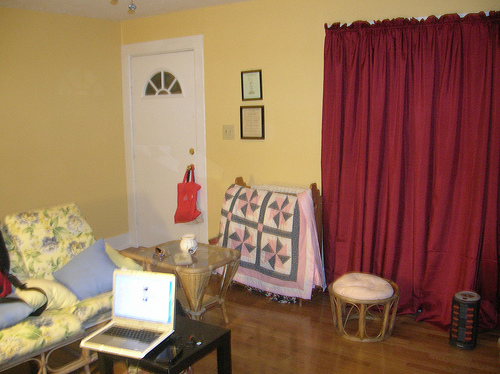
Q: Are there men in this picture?
A: No, there are no men.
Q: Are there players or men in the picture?
A: No, there are no men or players.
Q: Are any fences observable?
A: No, there are no fences.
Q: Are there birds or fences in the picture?
A: No, there are no fences or birds.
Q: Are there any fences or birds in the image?
A: No, there are no fences or birds.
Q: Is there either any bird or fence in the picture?
A: No, there are no fences or birds.